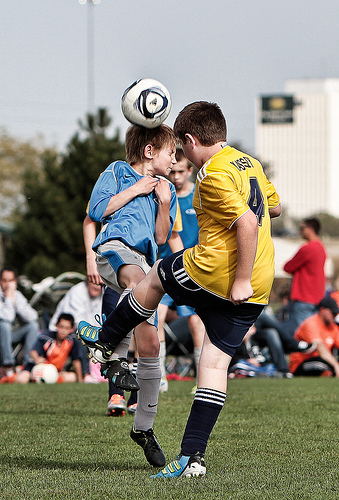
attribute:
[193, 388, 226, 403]
stripe — white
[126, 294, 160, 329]
stripes — white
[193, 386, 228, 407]
stripe — white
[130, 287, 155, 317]
stripe — white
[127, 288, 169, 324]
stripe — white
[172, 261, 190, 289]
stripe — white